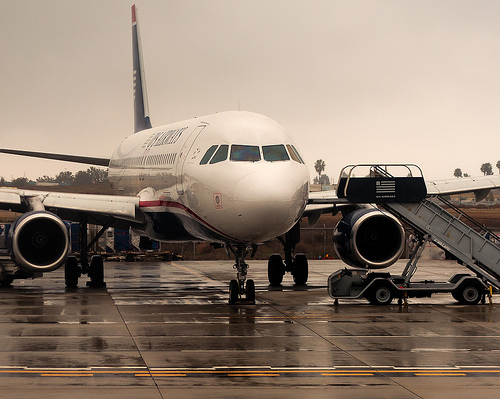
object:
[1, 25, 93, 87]
sky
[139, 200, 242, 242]
stripe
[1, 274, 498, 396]
ground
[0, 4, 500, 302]
airplane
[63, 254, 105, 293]
tires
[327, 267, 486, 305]
wheels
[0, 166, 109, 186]
trees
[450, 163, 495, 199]
tree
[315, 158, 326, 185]
tree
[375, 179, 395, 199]
logo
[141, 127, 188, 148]
logo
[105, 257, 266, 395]
platform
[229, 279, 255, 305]
blocks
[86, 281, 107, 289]
blocks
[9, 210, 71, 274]
engine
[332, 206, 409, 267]
engine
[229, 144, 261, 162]
window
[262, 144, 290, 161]
window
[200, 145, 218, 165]
window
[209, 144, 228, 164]
window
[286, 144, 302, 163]
window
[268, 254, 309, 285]
wheel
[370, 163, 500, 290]
ramp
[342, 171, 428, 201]
partition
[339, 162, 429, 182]
railings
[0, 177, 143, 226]
wing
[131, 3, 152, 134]
tail